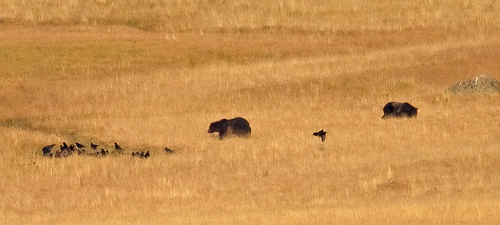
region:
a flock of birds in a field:
[40, 136, 175, 159]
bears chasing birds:
[36, 98, 418, 163]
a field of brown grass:
[1, 0, 496, 215]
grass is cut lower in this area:
[0, 32, 493, 72]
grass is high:
[0, 0, 486, 31]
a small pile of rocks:
[441, 70, 496, 96]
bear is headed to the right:
[381, 86, 417, 121]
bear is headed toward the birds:
[205, 110, 263, 145]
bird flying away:
[308, 125, 335, 143]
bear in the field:
[380, 102, 422, 128]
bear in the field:
[195, 110, 267, 148]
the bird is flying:
[310, 129, 343, 144]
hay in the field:
[175, 155, 320, 182]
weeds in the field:
[42, 92, 118, 114]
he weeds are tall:
[223, 174, 303, 196]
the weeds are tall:
[100, 0, 175, 25]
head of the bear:
[202, 115, 218, 137]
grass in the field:
[8, 106, 85, 136]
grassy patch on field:
[21, 34, 114, 74]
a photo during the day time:
[10, 5, 492, 212]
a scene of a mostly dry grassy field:
[5, 6, 491, 213]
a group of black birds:
[30, 130, 189, 164]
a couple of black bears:
[200, 99, 422, 143]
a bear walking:
[204, 104, 257, 154]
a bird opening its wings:
[305, 118, 338, 154]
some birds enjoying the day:
[29, 131, 187, 167]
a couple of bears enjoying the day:
[200, 80, 422, 157]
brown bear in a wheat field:
[202, 114, 253, 144]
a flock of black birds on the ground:
[25, 121, 186, 171]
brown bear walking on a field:
[372, 91, 420, 126]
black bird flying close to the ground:
[307, 126, 330, 143]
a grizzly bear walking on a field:
[202, 112, 257, 141]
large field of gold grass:
[0, 60, 496, 219]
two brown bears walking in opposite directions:
[209, 98, 425, 142]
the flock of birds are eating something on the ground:
[29, 135, 179, 160]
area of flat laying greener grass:
[0, 31, 237, 78]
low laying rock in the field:
[442, 66, 498, 101]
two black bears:
[207, 96, 422, 138]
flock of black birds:
[42, 133, 174, 163]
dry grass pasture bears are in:
[2, 4, 499, 216]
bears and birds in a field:
[40, 99, 428, 174]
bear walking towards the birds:
[201, 113, 255, 144]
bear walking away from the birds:
[382, 99, 422, 124]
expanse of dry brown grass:
[5, 9, 494, 217]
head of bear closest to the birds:
[207, 119, 219, 137]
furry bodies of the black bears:
[209, 97, 418, 135]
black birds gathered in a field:
[36, 139, 179, 160]